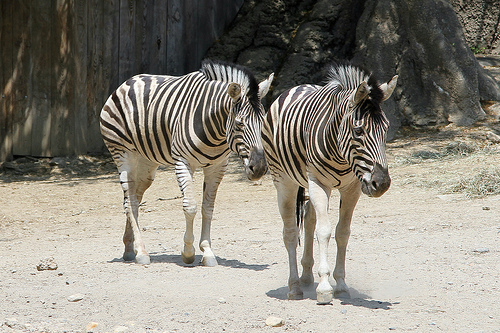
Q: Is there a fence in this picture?
A: Yes, there is a fence.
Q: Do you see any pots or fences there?
A: Yes, there is a fence.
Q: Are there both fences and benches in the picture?
A: No, there is a fence but no benches.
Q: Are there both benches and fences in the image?
A: No, there is a fence but no benches.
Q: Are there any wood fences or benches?
A: Yes, there is a wood fence.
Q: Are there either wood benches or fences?
A: Yes, there is a wood fence.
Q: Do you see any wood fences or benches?
A: Yes, there is a wood fence.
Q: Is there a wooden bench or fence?
A: Yes, there is a wood fence.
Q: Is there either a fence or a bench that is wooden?
A: Yes, the fence is wooden.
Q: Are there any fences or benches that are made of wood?
A: Yes, the fence is made of wood.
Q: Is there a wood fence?
A: Yes, there is a fence that is made of wood.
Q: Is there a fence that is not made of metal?
A: Yes, there is a fence that is made of wood.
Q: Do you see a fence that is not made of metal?
A: Yes, there is a fence that is made of wood.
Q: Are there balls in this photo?
A: No, there are no balls.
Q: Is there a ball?
A: No, there are no balls.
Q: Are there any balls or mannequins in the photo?
A: No, there are no balls or mannequins.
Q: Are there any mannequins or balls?
A: No, there are no balls or mannequins.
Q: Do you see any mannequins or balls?
A: No, there are no balls or mannequins.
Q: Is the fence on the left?
A: Yes, the fence is on the left of the image.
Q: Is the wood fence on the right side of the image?
A: No, the fence is on the left of the image.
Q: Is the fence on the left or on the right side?
A: The fence is on the left of the image.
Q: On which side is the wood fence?
A: The fence is on the left of the image.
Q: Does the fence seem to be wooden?
A: Yes, the fence is wooden.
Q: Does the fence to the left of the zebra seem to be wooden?
A: Yes, the fence is wooden.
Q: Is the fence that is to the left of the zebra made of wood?
A: Yes, the fence is made of wood.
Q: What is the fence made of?
A: The fence is made of wood.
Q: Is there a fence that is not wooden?
A: No, there is a fence but it is wooden.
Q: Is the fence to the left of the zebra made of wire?
A: No, the fence is made of wood.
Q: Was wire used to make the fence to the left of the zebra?
A: No, the fence is made of wood.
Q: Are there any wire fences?
A: No, there is a fence but it is made of wood.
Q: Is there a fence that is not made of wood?
A: No, there is a fence but it is made of wood.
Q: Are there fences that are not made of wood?
A: No, there is a fence but it is made of wood.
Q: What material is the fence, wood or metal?
A: The fence is made of wood.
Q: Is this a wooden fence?
A: Yes, this is a wooden fence.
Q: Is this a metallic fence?
A: No, this is a wooden fence.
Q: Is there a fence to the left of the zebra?
A: Yes, there is a fence to the left of the zebra.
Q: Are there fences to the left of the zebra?
A: Yes, there is a fence to the left of the zebra.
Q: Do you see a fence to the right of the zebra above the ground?
A: No, the fence is to the left of the zebra.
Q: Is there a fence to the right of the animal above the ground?
A: No, the fence is to the left of the zebra.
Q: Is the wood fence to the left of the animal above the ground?
A: Yes, the fence is to the left of the zebra.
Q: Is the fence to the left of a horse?
A: No, the fence is to the left of the zebra.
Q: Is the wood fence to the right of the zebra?
A: No, the fence is to the left of the zebra.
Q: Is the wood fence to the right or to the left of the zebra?
A: The fence is to the left of the zebra.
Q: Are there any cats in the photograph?
A: No, there are no cats.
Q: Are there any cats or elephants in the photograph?
A: No, there are no cats or elephants.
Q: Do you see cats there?
A: No, there are no cats.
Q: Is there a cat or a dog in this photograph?
A: No, there are no cats or dogs.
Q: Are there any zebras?
A: Yes, there is a zebra.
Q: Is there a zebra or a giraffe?
A: Yes, there is a zebra.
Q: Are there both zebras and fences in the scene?
A: Yes, there are both a zebra and a fence.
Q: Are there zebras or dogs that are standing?
A: Yes, the zebra is standing.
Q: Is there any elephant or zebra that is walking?
A: Yes, the zebra is walking.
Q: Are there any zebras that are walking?
A: Yes, there is a zebra that is walking.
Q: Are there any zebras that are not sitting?
A: Yes, there is a zebra that is walking.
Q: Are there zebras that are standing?
A: Yes, there is a zebra that is standing.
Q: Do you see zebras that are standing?
A: Yes, there is a zebra that is standing.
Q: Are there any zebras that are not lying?
A: Yes, there is a zebra that is standing.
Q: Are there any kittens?
A: No, there are no kittens.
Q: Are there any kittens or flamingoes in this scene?
A: No, there are no kittens or flamingoes.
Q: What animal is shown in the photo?
A: The animal is a zebra.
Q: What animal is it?
A: The animal is a zebra.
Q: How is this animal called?
A: This is a zebra.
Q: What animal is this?
A: This is a zebra.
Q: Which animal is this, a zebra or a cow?
A: This is a zebra.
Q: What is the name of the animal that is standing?
A: The animal is a zebra.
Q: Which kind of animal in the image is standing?
A: The animal is a zebra.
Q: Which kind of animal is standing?
A: The animal is a zebra.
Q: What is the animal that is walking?
A: The animal is a zebra.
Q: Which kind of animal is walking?
A: The animal is a zebra.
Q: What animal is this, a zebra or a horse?
A: This is a zebra.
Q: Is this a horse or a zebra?
A: This is a zebra.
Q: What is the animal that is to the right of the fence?
A: The animal is a zebra.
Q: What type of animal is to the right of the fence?
A: The animal is a zebra.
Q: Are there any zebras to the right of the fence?
A: Yes, there is a zebra to the right of the fence.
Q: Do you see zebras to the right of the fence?
A: Yes, there is a zebra to the right of the fence.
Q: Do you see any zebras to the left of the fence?
A: No, the zebra is to the right of the fence.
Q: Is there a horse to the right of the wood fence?
A: No, there is a zebra to the right of the fence.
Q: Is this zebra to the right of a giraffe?
A: No, the zebra is to the right of the fence.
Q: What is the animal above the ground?
A: The animal is a zebra.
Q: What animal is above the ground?
A: The animal is a zebra.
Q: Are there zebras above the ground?
A: Yes, there is a zebra above the ground.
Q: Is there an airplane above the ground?
A: No, there is a zebra above the ground.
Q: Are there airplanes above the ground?
A: No, there is a zebra above the ground.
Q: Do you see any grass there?
A: Yes, there is grass.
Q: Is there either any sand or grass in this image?
A: Yes, there is grass.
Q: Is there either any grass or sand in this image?
A: Yes, there is grass.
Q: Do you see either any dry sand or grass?
A: Yes, there is dry grass.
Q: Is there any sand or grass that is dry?
A: Yes, the grass is dry.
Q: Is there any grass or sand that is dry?
A: Yes, the grass is dry.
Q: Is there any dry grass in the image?
A: Yes, there is dry grass.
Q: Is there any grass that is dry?
A: Yes, there is grass that is dry.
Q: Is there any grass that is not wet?
A: Yes, there is dry grass.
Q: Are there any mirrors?
A: No, there are no mirrors.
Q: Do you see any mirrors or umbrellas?
A: No, there are no mirrors or umbrellas.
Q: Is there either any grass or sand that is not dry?
A: No, there is grass but it is dry.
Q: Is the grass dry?
A: Yes, the grass is dry.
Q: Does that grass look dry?
A: Yes, the grass is dry.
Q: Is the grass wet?
A: No, the grass is dry.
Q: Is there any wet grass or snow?
A: No, there is grass but it is dry.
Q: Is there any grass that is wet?
A: No, there is grass but it is dry.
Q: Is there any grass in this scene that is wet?
A: No, there is grass but it is dry.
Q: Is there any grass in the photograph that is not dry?
A: No, there is grass but it is dry.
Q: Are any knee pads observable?
A: No, there are no knee pads.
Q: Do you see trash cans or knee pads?
A: No, there are no knee pads or trash cans.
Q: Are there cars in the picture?
A: No, there are no cars.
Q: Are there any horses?
A: No, there are no horses.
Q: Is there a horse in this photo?
A: No, there are no horses.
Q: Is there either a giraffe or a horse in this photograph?
A: No, there are no horses or giraffes.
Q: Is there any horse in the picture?
A: No, there are no horses.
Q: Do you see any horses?
A: No, there are no horses.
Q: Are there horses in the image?
A: No, there are no horses.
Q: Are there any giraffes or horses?
A: No, there are no horses or giraffes.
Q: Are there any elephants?
A: No, there are no elephants.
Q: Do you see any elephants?
A: No, there are no elephants.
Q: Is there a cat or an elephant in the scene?
A: No, there are no elephants or cats.